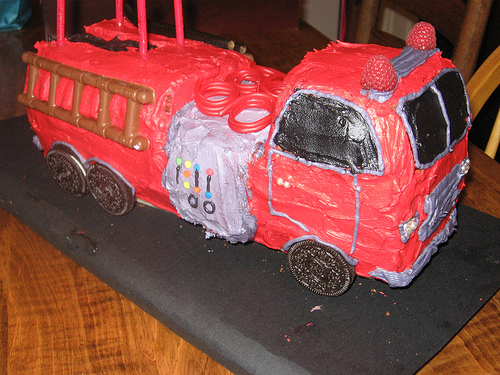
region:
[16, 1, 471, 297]
A cake made to look like a fire truck.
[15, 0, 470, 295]
Red frosted fire truck cake.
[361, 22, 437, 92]
Raspberries used for the fire truck lights.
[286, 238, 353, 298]
An Oreo cookie wheel.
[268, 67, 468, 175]
Black and silver frosting windows.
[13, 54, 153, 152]
Brown frosting ladder on the side of the truck.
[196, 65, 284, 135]
Red string licorice used for the fire hose.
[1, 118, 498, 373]
Black paper used for a road like setting.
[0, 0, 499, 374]
The cake is on top of a brown wooden table.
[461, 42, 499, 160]
Edge of a wooden chair next to the cake.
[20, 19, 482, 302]
A cake in the shape of a firetruck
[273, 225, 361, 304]
A wheel in the form of a Oreo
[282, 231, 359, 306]
The wheel is a Oreo cookie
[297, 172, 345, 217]
Red frosting on a cake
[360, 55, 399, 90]
A berry on a cake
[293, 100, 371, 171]
The window has black colored frosting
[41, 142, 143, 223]
Two Oreo cookies on a cake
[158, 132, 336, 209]
A cake with red, silver and black frosting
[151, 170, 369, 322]
The cake is on a black platform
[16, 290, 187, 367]
The platform is on a wooden table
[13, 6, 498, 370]
a red cake in the shape of a firetruck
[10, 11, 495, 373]
a scene inside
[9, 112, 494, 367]
a black plate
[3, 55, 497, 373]
a brown table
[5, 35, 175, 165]
a brown ladder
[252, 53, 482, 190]
three black windows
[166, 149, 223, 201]
some multicolored buttons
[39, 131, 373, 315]
black tires on firetruck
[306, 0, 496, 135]
a brown chair in the background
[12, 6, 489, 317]
one red firetruck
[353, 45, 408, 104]
a piece of fruit on a cake.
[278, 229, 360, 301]
a cookie on a cake.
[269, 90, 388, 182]
a frosting window on a cake.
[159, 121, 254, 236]
a frosting control panel.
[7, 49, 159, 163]
a chocolate ladder.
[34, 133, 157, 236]
cookies made to look like wheels.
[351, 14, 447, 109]
fruit made to look like emergency lights.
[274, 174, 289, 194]
frosting made to look like a door.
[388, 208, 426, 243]
frosting made to look like a head light.